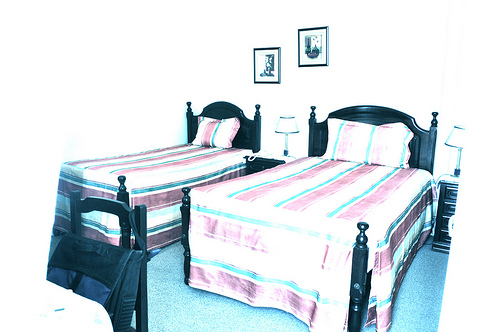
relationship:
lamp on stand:
[249, 107, 323, 168] [238, 136, 302, 188]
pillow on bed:
[317, 112, 417, 170] [176, 99, 440, 329]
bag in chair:
[42, 230, 145, 331] [63, 188, 147, 248]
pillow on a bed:
[192, 112, 242, 147] [54, 95, 269, 260]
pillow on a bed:
[318, 116, 416, 170] [176, 99, 440, 329]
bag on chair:
[42, 217, 147, 330] [65, 182, 155, 329]